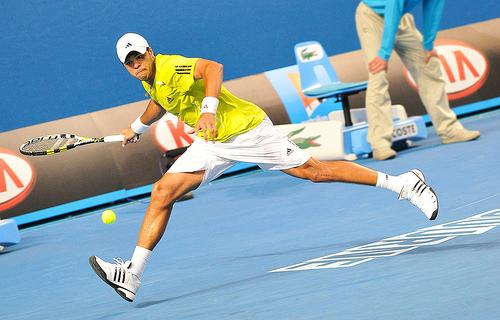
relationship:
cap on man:
[113, 32, 150, 64] [87, 30, 438, 302]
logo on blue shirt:
[398, 23, 496, 115] [360, 0, 447, 63]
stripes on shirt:
[173, 62, 190, 76] [138, 56, 270, 145]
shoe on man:
[403, 168, 442, 223] [87, 30, 438, 302]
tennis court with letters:
[0, 74, 499, 318] [262, 207, 497, 277]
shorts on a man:
[166, 111, 307, 188] [86, 30, 440, 304]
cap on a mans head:
[115, 32, 150, 63] [115, 32, 153, 81]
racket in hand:
[18, 120, 144, 178] [115, 118, 143, 148]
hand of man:
[115, 118, 143, 148] [105, 21, 326, 278]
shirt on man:
[138, 56, 270, 145] [87, 30, 438, 302]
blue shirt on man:
[360, 0, 457, 64] [352, 1, 481, 161]